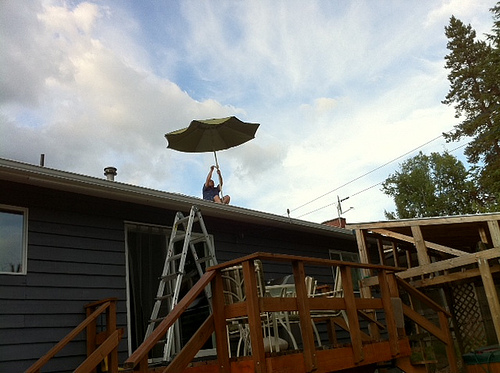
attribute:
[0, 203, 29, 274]
window frame — white 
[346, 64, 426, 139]
clouds — white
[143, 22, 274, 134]
sky — blue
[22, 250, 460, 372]
deck — wooden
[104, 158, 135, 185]
vent — metal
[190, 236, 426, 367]
railing — brown, wooden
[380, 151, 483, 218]
leaves — green, brown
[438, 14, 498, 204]
tree — brown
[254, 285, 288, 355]
table — white, patio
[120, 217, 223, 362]
doors — glass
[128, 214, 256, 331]
ladder — silver, open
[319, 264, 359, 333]
chair — white, patio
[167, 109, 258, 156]
umbrella — green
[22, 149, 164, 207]
gutter — white, metal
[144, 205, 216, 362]
ladder — tall, metal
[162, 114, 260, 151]
umbrella — yellow 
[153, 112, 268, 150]
umbrella — large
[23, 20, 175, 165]
clouds — white, large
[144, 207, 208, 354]
ladder — silver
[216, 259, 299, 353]
furniture — white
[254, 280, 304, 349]
furniture — white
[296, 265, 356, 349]
furniture — white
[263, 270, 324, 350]
furniture — white